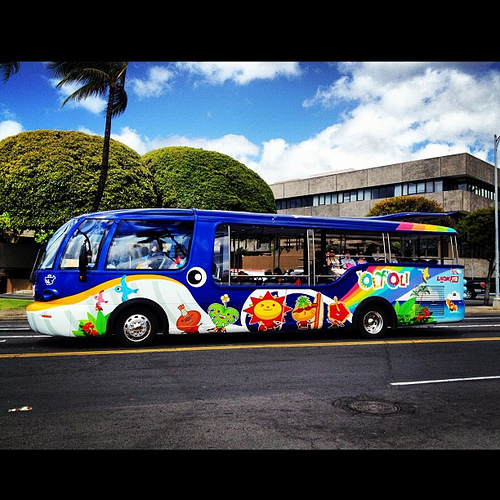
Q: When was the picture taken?
A: Daytime.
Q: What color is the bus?
A: Blue, white, and yellow.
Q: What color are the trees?
A: Green.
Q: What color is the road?
A: Black.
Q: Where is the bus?
A: On the road.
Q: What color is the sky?
A: Blue.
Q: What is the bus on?
A: The road.